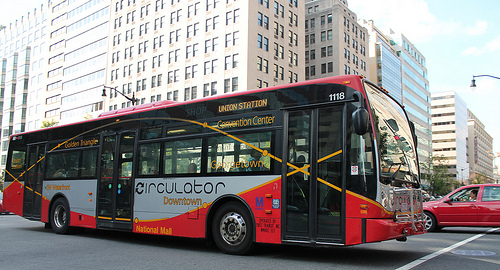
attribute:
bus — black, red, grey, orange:
[0, 74, 427, 253]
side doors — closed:
[283, 105, 346, 245]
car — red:
[423, 182, 497, 231]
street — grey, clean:
[0, 250, 497, 270]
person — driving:
[468, 187, 478, 203]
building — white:
[2, 1, 103, 118]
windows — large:
[433, 120, 456, 127]